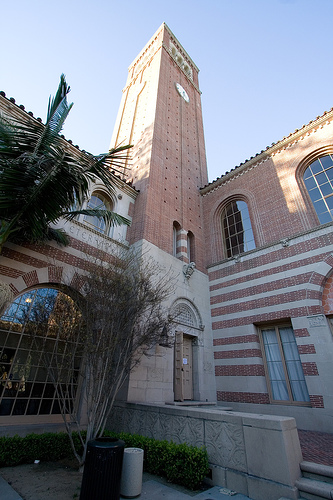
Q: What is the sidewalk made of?
A: Concrete.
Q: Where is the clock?
A: Top of the tower.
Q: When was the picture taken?
A: Daytime.